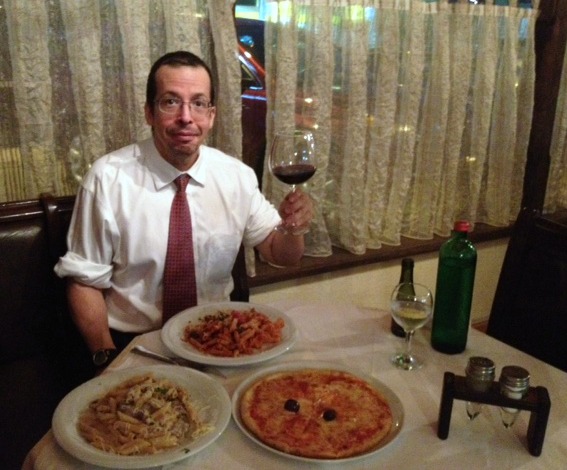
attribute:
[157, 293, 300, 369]
plate — dinner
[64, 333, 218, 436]
plate — white